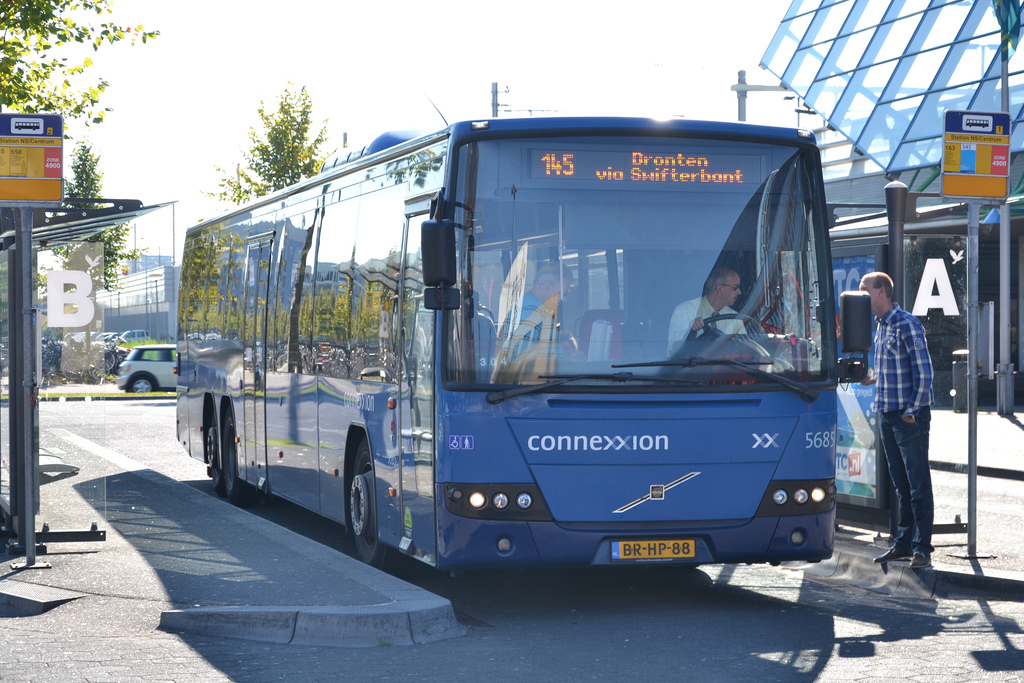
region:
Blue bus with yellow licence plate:
[166, 107, 849, 591]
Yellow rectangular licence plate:
[613, 533, 702, 563]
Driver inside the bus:
[664, 260, 757, 369]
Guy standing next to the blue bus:
[855, 266, 939, 576]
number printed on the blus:
[539, 146, 578, 179]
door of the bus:
[234, 225, 282, 491]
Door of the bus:
[386, 183, 443, 566]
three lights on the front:
[465, 486, 533, 513]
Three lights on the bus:
[771, 481, 829, 505]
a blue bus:
[160, 102, 860, 597]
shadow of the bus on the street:
[64, 463, 848, 679]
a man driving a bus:
[655, 258, 767, 357]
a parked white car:
[106, 333, 183, 403]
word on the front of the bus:
[519, 423, 682, 459]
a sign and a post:
[936, 102, 1019, 568]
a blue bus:
[357, 119, 817, 554]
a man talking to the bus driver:
[841, 220, 979, 581]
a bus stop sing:
[919, 102, 1011, 245]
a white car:
[116, 337, 192, 432]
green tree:
[227, 75, 341, 221]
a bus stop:
[8, 161, 234, 589]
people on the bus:
[511, 256, 587, 367]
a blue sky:
[84, 37, 269, 205]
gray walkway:
[35, 505, 250, 646]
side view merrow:
[375, 184, 473, 371]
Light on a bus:
[462, 486, 486, 515]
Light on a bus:
[486, 487, 512, 514]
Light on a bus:
[793, 489, 812, 505]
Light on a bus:
[811, 483, 827, 506]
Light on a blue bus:
[461, 490, 490, 511]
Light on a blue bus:
[492, 490, 511, 514]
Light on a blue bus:
[514, 489, 537, 516]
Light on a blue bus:
[773, 486, 793, 509]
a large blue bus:
[170, 120, 842, 579]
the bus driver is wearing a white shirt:
[666, 265, 788, 357]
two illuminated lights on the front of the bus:
[455, 484, 832, 507]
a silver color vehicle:
[111, 341, 175, 393]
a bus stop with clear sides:
[5, 190, 179, 539]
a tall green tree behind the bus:
[202, 73, 346, 214]